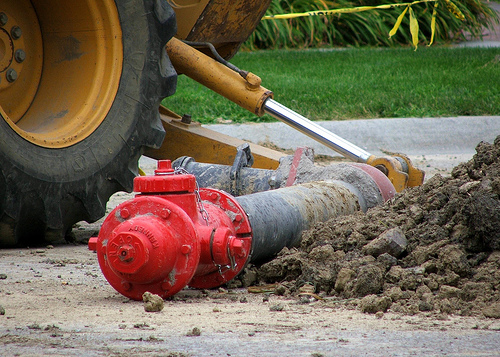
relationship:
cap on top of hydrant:
[83, 192, 173, 278] [76, 112, 440, 276]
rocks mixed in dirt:
[140, 132, 497, 337] [238, 129, 498, 321]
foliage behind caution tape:
[242, 0, 497, 49] [260, 0, 441, 48]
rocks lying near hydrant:
[70, 212, 253, 307] [82, 206, 224, 293]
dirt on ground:
[0, 130, 499, 357] [1, 40, 498, 355]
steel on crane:
[230, 80, 372, 195] [0, 2, 428, 238]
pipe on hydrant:
[171, 158, 424, 289] [86, 160, 251, 299]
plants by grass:
[262, 5, 486, 61] [249, 37, 489, 121]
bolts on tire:
[2, 11, 34, 92] [0, 0, 174, 246]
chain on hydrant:
[157, 164, 207, 214] [86, 160, 251, 299]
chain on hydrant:
[195, 181, 210, 226] [88, 142, 241, 304]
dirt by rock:
[0, 130, 499, 357] [47, 287, 283, 343]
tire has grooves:
[0, 0, 174, 246] [140, 2, 180, 164]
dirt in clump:
[259, 130, 499, 325] [358, 222, 415, 260]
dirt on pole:
[0, 130, 499, 357] [165, 156, 397, 276]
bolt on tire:
[9, 23, 25, 42] [0, 0, 174, 246]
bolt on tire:
[13, 46, 29, 61] [0, 0, 174, 246]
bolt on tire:
[4, 69, 16, 84] [0, 0, 174, 246]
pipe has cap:
[87, 149, 411, 300] [88, 162, 251, 302]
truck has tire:
[0, 0, 426, 247] [0, 0, 174, 246]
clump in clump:
[141, 291, 164, 313] [139, 289, 166, 315]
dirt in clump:
[0, 130, 499, 357] [139, 289, 166, 315]